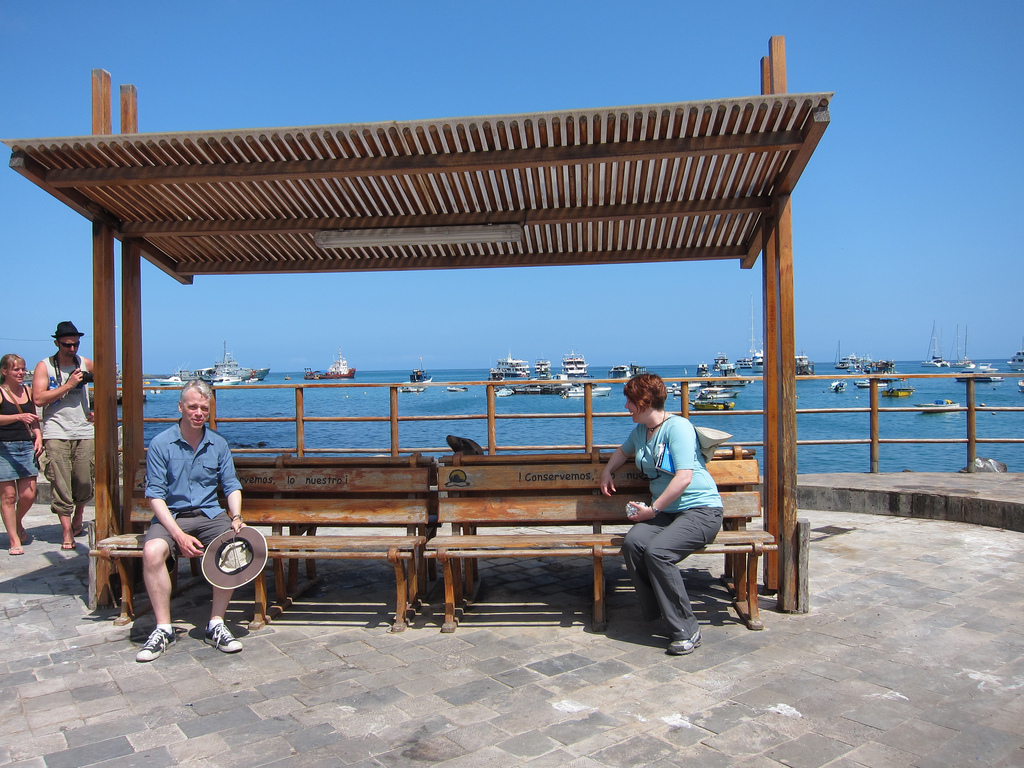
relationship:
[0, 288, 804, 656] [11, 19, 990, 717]
people enjoying outdoors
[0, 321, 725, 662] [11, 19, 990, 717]
people enjoying outdoors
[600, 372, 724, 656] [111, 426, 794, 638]
woman sitting bench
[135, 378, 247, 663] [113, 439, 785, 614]
man sitting bench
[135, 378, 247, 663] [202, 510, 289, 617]
man holding hat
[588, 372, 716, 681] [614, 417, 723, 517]
woman wearing top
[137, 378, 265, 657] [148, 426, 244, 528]
man wearing shirt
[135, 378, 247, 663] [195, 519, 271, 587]
man holding hat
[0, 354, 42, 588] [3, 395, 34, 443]
woman wearing top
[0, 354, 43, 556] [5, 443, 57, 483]
woman wearing skirt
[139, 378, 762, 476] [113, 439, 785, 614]
railing on bench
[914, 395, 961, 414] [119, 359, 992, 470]
boat on water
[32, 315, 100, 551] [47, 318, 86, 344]
man wearing a hat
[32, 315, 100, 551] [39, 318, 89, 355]
man wearing hat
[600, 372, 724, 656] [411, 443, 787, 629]
woman sitting on bench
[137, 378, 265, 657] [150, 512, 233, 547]
man wearing shorts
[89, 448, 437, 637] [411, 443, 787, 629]
bench next to bench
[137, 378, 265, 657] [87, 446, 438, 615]
man sitting on bench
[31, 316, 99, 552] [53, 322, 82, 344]
man wearing hat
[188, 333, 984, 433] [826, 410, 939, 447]
boat on water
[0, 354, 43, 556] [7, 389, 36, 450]
woman wearing top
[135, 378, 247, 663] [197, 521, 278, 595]
man holding hat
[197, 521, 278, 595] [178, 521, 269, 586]
hat in hand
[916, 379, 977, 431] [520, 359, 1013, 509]
boat on water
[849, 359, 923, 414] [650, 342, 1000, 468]
boat on water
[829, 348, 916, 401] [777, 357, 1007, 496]
boat on water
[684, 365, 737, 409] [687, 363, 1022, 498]
boat on water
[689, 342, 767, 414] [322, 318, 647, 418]
boat on water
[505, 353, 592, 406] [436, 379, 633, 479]
boat on water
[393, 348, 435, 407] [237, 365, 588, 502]
boat on water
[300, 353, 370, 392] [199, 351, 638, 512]
boat on water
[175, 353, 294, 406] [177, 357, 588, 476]
boat on water